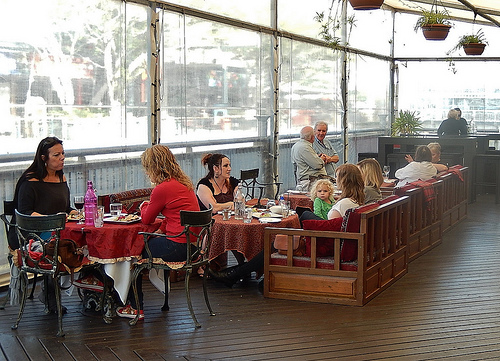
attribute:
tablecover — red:
[70, 205, 142, 265]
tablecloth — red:
[22, 202, 184, 303]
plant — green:
[313, 0, 359, 52]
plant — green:
[398, 0, 456, 32]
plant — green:
[445, 26, 489, 73]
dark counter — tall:
[376, 130, 474, 202]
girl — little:
[308, 173, 337, 206]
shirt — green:
[312, 201, 330, 213]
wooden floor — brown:
[217, 305, 498, 359]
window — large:
[1, 1, 151, 264]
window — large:
[159, 9, 266, 199]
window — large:
[279, 38, 341, 190]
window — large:
[346, 51, 389, 163]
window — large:
[394, 60, 499, 135]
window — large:
[395, 9, 499, 55]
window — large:
[346, 3, 395, 55]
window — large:
[276, 0, 344, 45]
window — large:
[159, 0, 272, 26]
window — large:
[383, 0, 497, 20]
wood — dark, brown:
[234, 304, 497, 359]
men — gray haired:
[287, 115, 344, 183]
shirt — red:
[132, 174, 206, 239]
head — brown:
[329, 164, 365, 225]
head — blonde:
[352, 159, 394, 204]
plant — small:
[388, 105, 420, 135]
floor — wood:
[1, 200, 498, 357]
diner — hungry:
[192, 151, 242, 220]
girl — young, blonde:
[309, 176, 341, 223]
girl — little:
[307, 177, 334, 218]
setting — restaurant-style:
[43, 65, 317, 295]